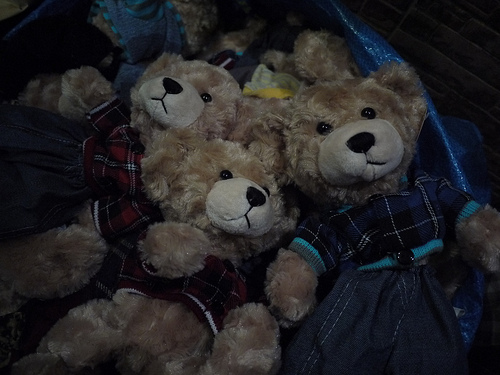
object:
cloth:
[287, 167, 499, 375]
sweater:
[287, 172, 486, 269]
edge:
[288, 236, 330, 279]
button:
[392, 249, 416, 268]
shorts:
[281, 260, 475, 374]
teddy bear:
[263, 63, 500, 373]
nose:
[345, 129, 379, 154]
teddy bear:
[0, 138, 302, 374]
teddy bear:
[3, 52, 263, 238]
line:
[382, 194, 405, 249]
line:
[344, 209, 374, 242]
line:
[384, 214, 450, 240]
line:
[417, 180, 441, 240]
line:
[297, 226, 340, 271]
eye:
[315, 119, 333, 134]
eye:
[358, 105, 378, 121]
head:
[265, 58, 429, 200]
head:
[159, 136, 291, 251]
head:
[126, 50, 247, 140]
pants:
[0, 101, 96, 238]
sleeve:
[287, 208, 346, 271]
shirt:
[80, 95, 165, 243]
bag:
[0, 3, 488, 374]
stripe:
[110, 284, 218, 337]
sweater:
[108, 235, 261, 329]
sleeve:
[428, 174, 488, 227]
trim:
[450, 199, 483, 231]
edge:
[322, 1, 493, 375]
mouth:
[352, 156, 387, 178]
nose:
[239, 183, 269, 211]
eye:
[218, 167, 234, 179]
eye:
[262, 182, 271, 198]